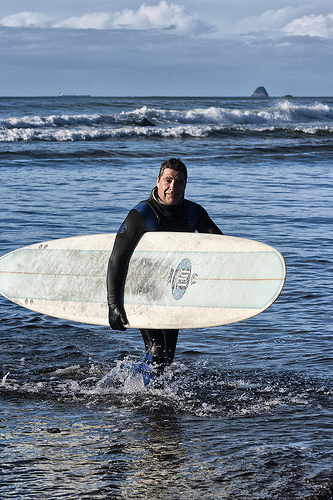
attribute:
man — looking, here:
[107, 159, 225, 383]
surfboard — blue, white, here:
[3, 232, 285, 329]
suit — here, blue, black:
[106, 189, 224, 385]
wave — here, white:
[1, 100, 333, 144]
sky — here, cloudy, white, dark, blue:
[1, 0, 333, 96]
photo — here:
[1, 0, 331, 498]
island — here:
[251, 85, 270, 99]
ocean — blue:
[1, 95, 333, 499]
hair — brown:
[159, 158, 188, 185]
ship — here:
[280, 93, 294, 99]